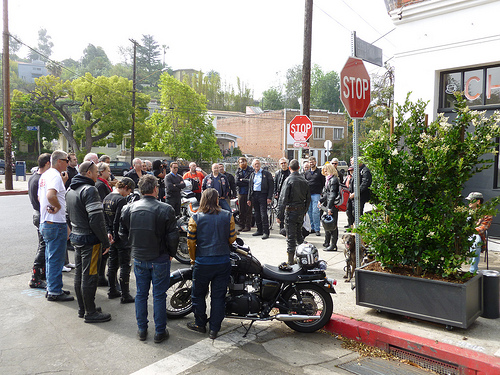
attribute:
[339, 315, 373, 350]
paint — red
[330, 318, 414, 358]
paint — red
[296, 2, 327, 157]
post — gray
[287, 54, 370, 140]
stop signs — red, white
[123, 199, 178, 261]
jacket — black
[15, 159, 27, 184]
mailbox — blue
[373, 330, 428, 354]
curb — red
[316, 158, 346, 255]
woman — blonde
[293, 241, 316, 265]
helmet — black 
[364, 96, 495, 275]
shrub — green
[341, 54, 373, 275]
sign — red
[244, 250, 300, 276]
seat — black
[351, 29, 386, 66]
sign — stop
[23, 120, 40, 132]
sign — stop